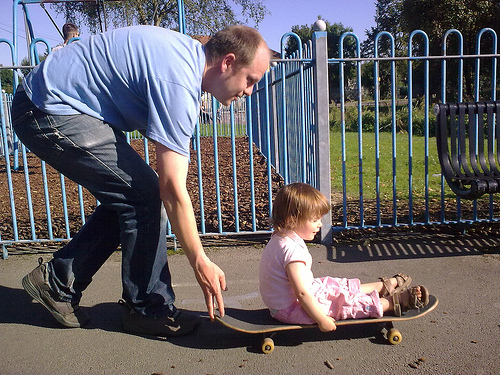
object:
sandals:
[375, 268, 427, 312]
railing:
[0, 12, 498, 260]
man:
[4, 21, 271, 339]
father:
[8, 25, 270, 339]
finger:
[203, 293, 215, 319]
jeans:
[3, 92, 168, 312]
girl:
[257, 185, 429, 322]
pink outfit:
[260, 232, 384, 321]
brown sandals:
[379, 270, 430, 312]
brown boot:
[20, 262, 94, 335]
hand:
[315, 310, 345, 340]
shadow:
[318, 213, 478, 247]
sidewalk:
[16, 235, 496, 367]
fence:
[4, 29, 498, 254]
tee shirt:
[7, 6, 288, 162]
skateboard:
[215, 303, 442, 342]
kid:
[249, 179, 364, 311]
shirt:
[15, 38, 207, 154]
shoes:
[378, 275, 433, 315]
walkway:
[5, 228, 499, 374]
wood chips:
[302, 335, 499, 373]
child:
[260, 182, 428, 342]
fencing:
[5, 32, 496, 218]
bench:
[438, 98, 499, 211]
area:
[333, 128, 437, 199]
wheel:
[388, 326, 403, 346]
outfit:
[257, 231, 385, 324]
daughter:
[256, 182, 428, 329]